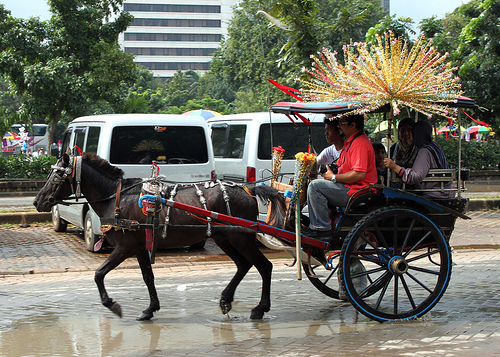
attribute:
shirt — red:
[341, 138, 370, 171]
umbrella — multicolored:
[436, 125, 493, 140]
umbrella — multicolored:
[0, 128, 24, 138]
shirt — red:
[330, 136, 377, 193]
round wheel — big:
[335, 200, 452, 322]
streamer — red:
[260, 77, 302, 102]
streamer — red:
[264, 75, 303, 95]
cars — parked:
[74, 92, 365, 220]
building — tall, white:
[108, 3, 254, 89]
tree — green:
[426, 1, 498, 133]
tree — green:
[209, 2, 405, 115]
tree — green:
[0, 4, 145, 127]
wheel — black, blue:
[331, 201, 456, 327]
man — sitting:
[303, 115, 378, 231]